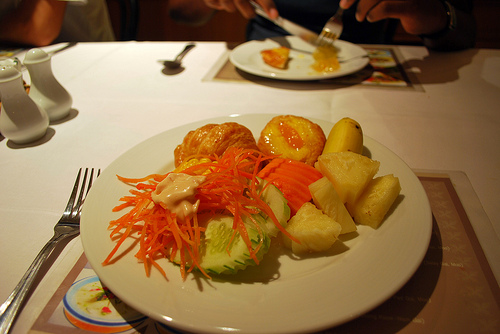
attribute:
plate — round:
[80, 114, 439, 333]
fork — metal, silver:
[3, 168, 102, 332]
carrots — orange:
[116, 160, 272, 264]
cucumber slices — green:
[188, 218, 271, 269]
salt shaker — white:
[2, 64, 49, 142]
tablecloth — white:
[4, 44, 496, 333]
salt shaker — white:
[26, 51, 73, 117]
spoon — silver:
[160, 43, 195, 74]